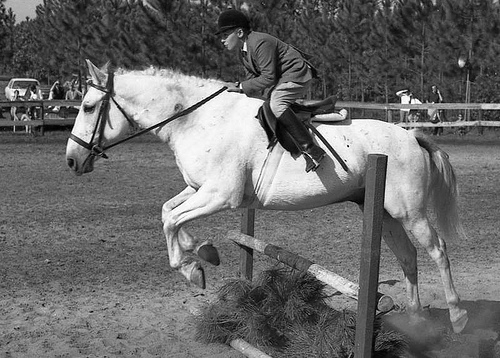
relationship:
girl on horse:
[204, 5, 336, 170] [62, 53, 483, 317]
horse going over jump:
[62, 53, 483, 317] [223, 149, 403, 354]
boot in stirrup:
[276, 107, 324, 177] [297, 149, 320, 171]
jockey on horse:
[217, 15, 329, 157] [39, 65, 482, 337]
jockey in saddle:
[213, 9, 327, 173] [254, 83, 349, 157]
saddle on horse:
[254, 83, 349, 157] [62, 53, 483, 317]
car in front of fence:
[3, 71, 41, 101] [4, 94, 79, 138]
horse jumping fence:
[62, 53, 483, 317] [224, 145, 406, 356]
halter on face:
[72, 70, 140, 164] [63, 62, 124, 178]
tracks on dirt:
[16, 215, 178, 355] [32, 267, 151, 355]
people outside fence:
[394, 82, 464, 132] [346, 98, 497, 147]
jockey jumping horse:
[213, 9, 327, 173] [62, 53, 483, 317]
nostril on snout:
[65, 154, 77, 171] [64, 150, 84, 178]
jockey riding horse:
[213, 9, 327, 173] [62, 53, 483, 317]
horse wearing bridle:
[62, 53, 483, 317] [91, 66, 117, 163]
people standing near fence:
[385, 83, 457, 143] [8, 83, 480, 136]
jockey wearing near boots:
[213, 9, 327, 173] [289, 131, 327, 171]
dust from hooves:
[351, 270, 499, 357] [399, 302, 476, 337]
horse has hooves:
[62, 53, 483, 317] [149, 223, 244, 300]